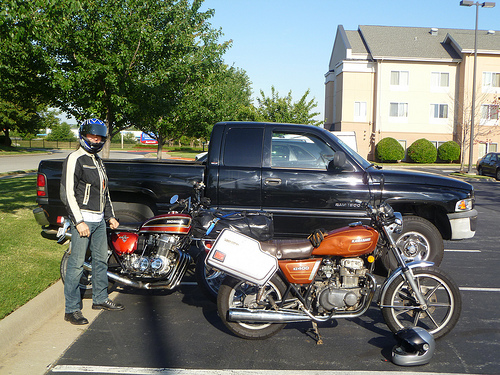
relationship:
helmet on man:
[75, 112, 107, 153] [74, 123, 128, 313]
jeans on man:
[73, 232, 109, 289] [74, 123, 128, 313]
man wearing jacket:
[74, 123, 128, 313] [70, 151, 119, 215]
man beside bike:
[74, 123, 128, 313] [244, 232, 460, 324]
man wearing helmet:
[74, 123, 128, 313] [75, 112, 107, 153]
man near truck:
[74, 123, 128, 313] [214, 123, 460, 213]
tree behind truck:
[129, 29, 200, 91] [214, 123, 460, 213]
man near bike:
[74, 123, 128, 313] [244, 232, 460, 324]